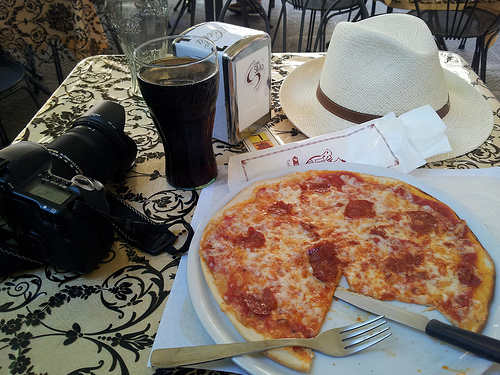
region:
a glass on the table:
[119, 36, 244, 216]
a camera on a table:
[1, 62, 136, 293]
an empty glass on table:
[92, 9, 231, 122]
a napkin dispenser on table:
[183, 11, 288, 169]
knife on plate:
[337, 278, 497, 355]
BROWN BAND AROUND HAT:
[331, 104, 343, 115]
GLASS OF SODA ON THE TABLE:
[131, 38, 219, 183]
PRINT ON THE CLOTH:
[103, 265, 154, 358]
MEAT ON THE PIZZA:
[341, 202, 373, 219]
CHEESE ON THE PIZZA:
[326, 208, 338, 227]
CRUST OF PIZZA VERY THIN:
[279, 352, 304, 359]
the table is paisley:
[19, 275, 154, 369]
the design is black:
[18, 267, 158, 362]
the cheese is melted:
[230, 192, 448, 329]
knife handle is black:
[433, 312, 498, 352]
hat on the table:
[290, 20, 481, 162]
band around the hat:
[318, 91, 454, 121]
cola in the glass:
[136, 62, 221, 197]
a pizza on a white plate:
[199, 145, 456, 368]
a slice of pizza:
[234, 258, 360, 361]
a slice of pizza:
[226, 180, 347, 262]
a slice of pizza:
[304, 165, 430, 271]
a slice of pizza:
[378, 183, 468, 254]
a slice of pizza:
[382, 230, 477, 301]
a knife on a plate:
[351, 284, 478, 372]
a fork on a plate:
[141, 304, 358, 373]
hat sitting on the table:
[289, 21, 469, 104]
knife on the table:
[391, 310, 427, 320]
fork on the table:
[168, 329, 358, 366]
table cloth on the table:
[53, 316, 97, 367]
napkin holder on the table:
[228, 37, 275, 140]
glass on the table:
[140, 38, 224, 198]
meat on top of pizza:
[346, 202, 377, 217]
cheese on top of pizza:
[270, 259, 300, 285]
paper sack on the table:
[311, 142, 368, 158]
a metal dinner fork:
[150, 312, 390, 369]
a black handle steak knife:
[335, 286, 498, 361]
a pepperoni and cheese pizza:
[198, 171, 494, 371]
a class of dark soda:
[132, 34, 221, 190]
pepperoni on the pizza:
[248, 287, 281, 317]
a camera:
[3, 131, 133, 256]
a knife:
[336, 284, 423, 333]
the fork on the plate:
[150, 315, 390, 371]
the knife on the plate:
[333, 278, 498, 363]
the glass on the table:
[130, 33, 221, 189]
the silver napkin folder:
[172, 19, 273, 144]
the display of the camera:
[30, 178, 71, 208]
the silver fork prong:
[340, 314, 383, 329]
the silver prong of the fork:
[340, 319, 387, 339]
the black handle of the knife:
[425, 316, 499, 362]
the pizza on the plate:
[200, 167, 494, 372]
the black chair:
[415, 1, 496, 80]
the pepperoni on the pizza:
[246, 286, 279, 316]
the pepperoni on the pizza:
[236, 225, 263, 250]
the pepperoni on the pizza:
[307, 239, 337, 261]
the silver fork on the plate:
[147, 314, 389, 367]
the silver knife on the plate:
[332, 280, 498, 363]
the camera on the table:
[1, 98, 134, 270]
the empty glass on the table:
[109, 1, 166, 98]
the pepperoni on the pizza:
[341, 198, 376, 220]